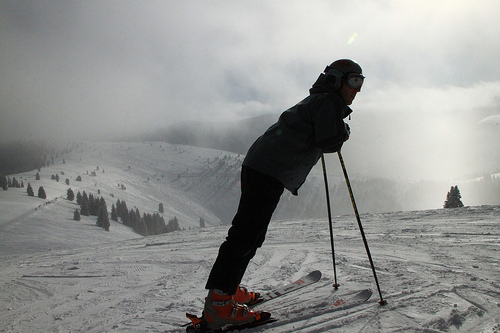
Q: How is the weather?
A: It is cloudy.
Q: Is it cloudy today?
A: Yes, it is cloudy.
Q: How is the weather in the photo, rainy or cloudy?
A: It is cloudy.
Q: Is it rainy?
A: No, it is cloudy.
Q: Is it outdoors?
A: Yes, it is outdoors.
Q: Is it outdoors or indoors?
A: It is outdoors.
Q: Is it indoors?
A: No, it is outdoors.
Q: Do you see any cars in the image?
A: No, there are no cars.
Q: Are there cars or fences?
A: No, there are no cars or fences.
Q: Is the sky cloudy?
A: Yes, the sky is cloudy.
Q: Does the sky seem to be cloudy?
A: Yes, the sky is cloudy.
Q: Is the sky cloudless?
A: No, the sky is cloudy.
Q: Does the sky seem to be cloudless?
A: No, the sky is cloudy.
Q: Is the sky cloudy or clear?
A: The sky is cloudy.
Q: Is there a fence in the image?
A: No, there are no fences.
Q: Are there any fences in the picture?
A: No, there are no fences.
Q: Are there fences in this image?
A: No, there are no fences.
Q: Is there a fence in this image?
A: No, there are no fences.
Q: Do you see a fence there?
A: No, there are no fences.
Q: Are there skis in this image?
A: Yes, there are skis.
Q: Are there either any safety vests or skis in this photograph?
A: Yes, there are skis.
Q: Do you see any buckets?
A: No, there are no buckets.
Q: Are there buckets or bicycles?
A: No, there are no buckets or bicycles.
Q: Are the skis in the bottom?
A: Yes, the skis are in the bottom of the image.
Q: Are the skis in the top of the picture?
A: No, the skis are in the bottom of the image.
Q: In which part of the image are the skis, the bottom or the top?
A: The skis are in the bottom of the image.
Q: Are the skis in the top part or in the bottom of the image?
A: The skis are in the bottom of the image.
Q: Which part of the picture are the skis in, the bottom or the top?
A: The skis are in the bottom of the image.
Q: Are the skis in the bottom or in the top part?
A: The skis are in the bottom of the image.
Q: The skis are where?
A: The skis are on the snow.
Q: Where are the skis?
A: The skis are on the snow.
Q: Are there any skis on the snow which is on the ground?
A: Yes, there are skis on the snow.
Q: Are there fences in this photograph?
A: No, there are no fences.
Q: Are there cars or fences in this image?
A: No, there are no fences or cars.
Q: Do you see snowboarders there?
A: No, there are no snowboarders.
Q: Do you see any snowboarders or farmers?
A: No, there are no snowboarders or farmers.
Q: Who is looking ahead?
A: The man is looking ahead.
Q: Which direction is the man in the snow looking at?
A: The man is looking ahead.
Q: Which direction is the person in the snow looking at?
A: The man is looking ahead.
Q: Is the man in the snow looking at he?
A: Yes, the man is looking ahead.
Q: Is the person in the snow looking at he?
A: Yes, the man is looking ahead.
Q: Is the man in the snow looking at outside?
A: No, the man is looking ahead.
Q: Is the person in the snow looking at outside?
A: No, the man is looking ahead.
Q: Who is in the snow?
A: The man is in the snow.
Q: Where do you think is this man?
A: The man is in the snow.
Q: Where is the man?
A: The man is in the snow.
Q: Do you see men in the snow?
A: Yes, there is a man in the snow.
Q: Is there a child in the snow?
A: No, there is a man in the snow.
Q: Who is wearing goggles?
A: The man is wearing goggles.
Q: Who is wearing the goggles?
A: The man is wearing goggles.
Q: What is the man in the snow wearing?
A: The man is wearing goggles.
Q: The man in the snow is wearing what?
A: The man is wearing goggles.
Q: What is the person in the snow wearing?
A: The man is wearing goggles.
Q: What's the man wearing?
A: The man is wearing goggles.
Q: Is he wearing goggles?
A: Yes, the man is wearing goggles.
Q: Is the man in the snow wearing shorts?
A: No, the man is wearing goggles.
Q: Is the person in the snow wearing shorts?
A: No, the man is wearing goggles.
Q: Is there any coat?
A: Yes, there is a coat.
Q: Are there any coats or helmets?
A: Yes, there is a coat.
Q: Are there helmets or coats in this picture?
A: Yes, there is a coat.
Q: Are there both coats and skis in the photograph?
A: Yes, there are both a coat and skis.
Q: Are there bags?
A: No, there are no bags.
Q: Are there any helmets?
A: Yes, there is a helmet.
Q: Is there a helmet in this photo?
A: Yes, there is a helmet.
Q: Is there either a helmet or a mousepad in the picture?
A: Yes, there is a helmet.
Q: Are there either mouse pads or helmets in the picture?
A: Yes, there is a helmet.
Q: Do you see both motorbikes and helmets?
A: No, there is a helmet but no motorcycles.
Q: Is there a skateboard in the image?
A: No, there are no skateboards.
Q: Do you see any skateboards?
A: No, there are no skateboards.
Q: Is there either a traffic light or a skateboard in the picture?
A: No, there are no skateboards or traffic lights.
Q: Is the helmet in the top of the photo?
A: Yes, the helmet is in the top of the image.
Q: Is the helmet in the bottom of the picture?
A: No, the helmet is in the top of the image.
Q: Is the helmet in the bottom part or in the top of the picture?
A: The helmet is in the top of the image.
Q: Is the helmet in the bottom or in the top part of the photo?
A: The helmet is in the top of the image.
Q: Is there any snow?
A: Yes, there is snow.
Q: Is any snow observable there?
A: Yes, there is snow.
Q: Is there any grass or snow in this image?
A: Yes, there is snow.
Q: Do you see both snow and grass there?
A: No, there is snow but no grass.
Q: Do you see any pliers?
A: No, there are no pliers.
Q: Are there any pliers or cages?
A: No, there are no pliers or cages.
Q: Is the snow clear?
A: Yes, the snow is clear.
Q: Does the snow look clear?
A: Yes, the snow is clear.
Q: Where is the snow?
A: The snow is on the ground.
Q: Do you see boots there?
A: Yes, there are boots.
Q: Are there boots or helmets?
A: Yes, there are boots.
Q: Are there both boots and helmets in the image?
A: Yes, there are both boots and a helmet.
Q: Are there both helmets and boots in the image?
A: Yes, there are both boots and a helmet.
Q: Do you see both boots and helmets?
A: Yes, there are both boots and a helmet.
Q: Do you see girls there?
A: No, there are no girls.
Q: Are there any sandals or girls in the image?
A: No, there are no girls or sandals.